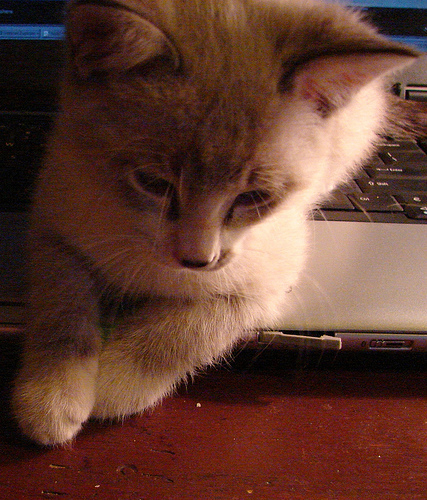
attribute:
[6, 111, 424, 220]
keyboard — black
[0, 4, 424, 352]
laptop — turned on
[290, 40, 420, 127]
ear — black rimmed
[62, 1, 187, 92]
ear — black rimmed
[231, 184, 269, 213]
eye — dark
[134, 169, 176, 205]
eye — dark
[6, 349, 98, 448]
paw — cute, crossed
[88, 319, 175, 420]
paw — cute, crossed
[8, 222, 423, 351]
surface — red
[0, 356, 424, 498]
table — red, wooden, brown, scratched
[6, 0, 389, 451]
fur — long, fuzzy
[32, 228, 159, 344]
whiskers — long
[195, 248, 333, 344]
whiskers — long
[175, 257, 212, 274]
nose — black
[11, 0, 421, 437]
kitten — sitting, adorable, cute, loeable, pretty, precious, lying, tan, white, down, tired